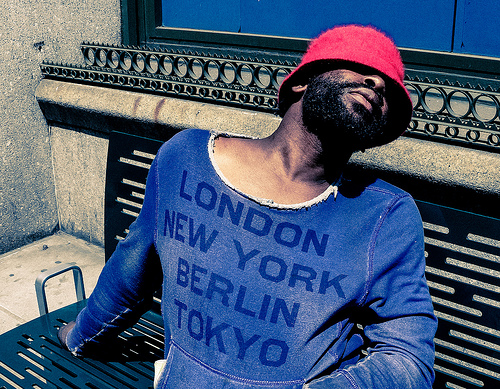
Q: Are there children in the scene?
A: No, there are no children.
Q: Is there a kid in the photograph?
A: No, there are no children.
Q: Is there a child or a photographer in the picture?
A: No, there are no children or photographers.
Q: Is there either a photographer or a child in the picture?
A: No, there are no children or photographers.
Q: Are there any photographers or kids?
A: No, there are no kids or photographers.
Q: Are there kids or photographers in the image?
A: No, there are no kids or photographers.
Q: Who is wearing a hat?
A: The man is wearing a hat.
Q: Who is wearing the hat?
A: The man is wearing a hat.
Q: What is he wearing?
A: The man is wearing a hat.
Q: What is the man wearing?
A: The man is wearing a hat.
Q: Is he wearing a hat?
A: Yes, the man is wearing a hat.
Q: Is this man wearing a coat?
A: No, the man is wearing a hat.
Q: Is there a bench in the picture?
A: Yes, there is a bench.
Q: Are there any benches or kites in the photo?
A: Yes, there is a bench.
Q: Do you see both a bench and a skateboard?
A: No, there is a bench but no skateboards.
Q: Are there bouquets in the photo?
A: No, there are no bouquets.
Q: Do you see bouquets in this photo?
A: No, there are no bouquets.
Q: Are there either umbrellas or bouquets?
A: No, there are no bouquets or umbrellas.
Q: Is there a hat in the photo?
A: Yes, there is a hat.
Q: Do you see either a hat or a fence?
A: Yes, there is a hat.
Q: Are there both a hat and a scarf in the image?
A: No, there is a hat but no scarves.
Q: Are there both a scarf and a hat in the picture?
A: No, there is a hat but no scarves.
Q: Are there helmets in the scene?
A: No, there are no helmets.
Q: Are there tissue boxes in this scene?
A: No, there are no tissue boxes.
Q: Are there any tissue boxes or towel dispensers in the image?
A: No, there are no tissue boxes or towel dispensers.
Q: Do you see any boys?
A: No, there are no boys.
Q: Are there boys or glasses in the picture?
A: No, there are no boys or glasses.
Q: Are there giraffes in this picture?
A: No, there are no giraffes.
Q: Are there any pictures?
A: No, there are no pictures.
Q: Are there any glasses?
A: No, there are no glasses.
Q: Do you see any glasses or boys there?
A: No, there are no glasses or boys.